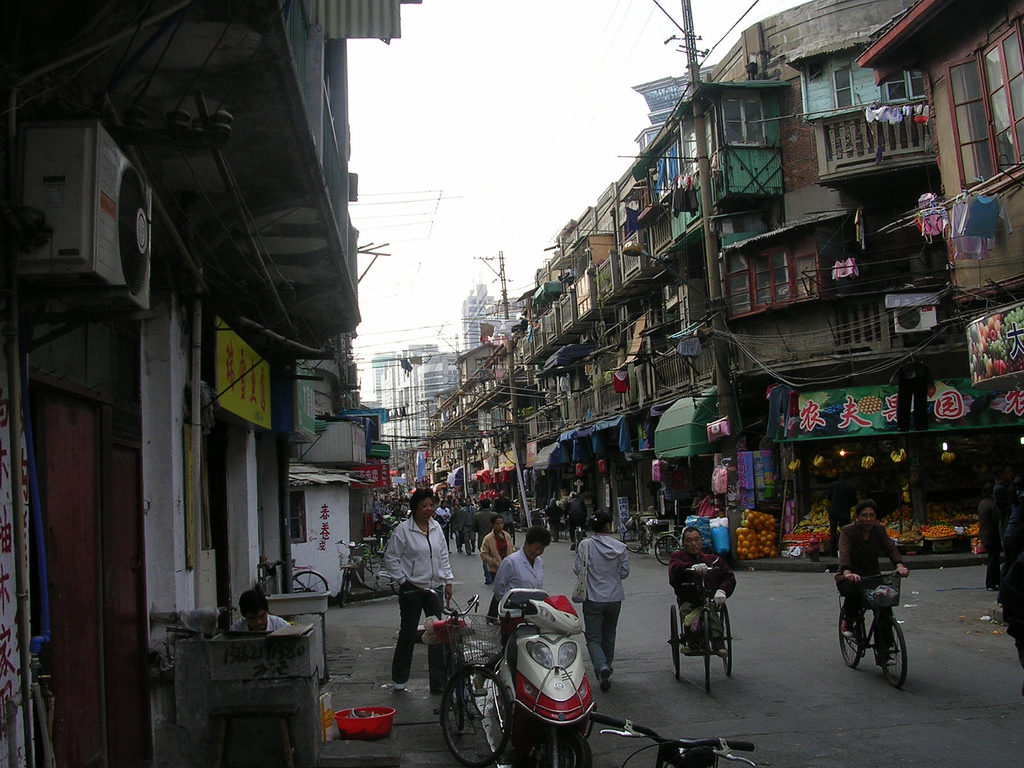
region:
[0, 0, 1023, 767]
An open day in busy street.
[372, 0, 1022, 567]
The street block on the right.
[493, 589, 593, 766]
A red and white colored motor bike.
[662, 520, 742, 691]
The person riding a tricycle.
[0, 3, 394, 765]
The street block on the left.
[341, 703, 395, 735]
A red basin on the street.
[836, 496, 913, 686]
The man cyclist on the right.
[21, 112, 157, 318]
An air conditioning equipment on the wall.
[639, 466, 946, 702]
people are riding bikes in the street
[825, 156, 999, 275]
clothes drying outside of window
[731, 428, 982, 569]
a fruit stand in the background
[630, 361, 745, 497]
a green awning on the building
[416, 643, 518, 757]
the wheel is black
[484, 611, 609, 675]
the headlights are off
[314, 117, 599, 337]
the sky is cloudy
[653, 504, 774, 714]
the bike has three wheels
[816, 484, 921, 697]
A man riding a bicycle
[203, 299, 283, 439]
Red writing on a yellow sign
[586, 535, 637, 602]
the sweater is gray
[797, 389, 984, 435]
the letters are chinese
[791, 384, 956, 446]
Chinese is on the sign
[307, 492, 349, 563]
characters on the building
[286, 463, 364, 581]
the building is shabby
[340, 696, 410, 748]
the container is on sidewalk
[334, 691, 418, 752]
the container is orange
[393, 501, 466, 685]
the person is standing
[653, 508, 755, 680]
man in sweatshirt pedaling cart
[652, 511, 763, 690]
man in sweatshirt pedaling cart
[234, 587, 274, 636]
Head of a man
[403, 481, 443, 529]
Head of a man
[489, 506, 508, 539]
Head of a woman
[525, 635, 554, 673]
Headlight of a motorcycle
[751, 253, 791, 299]
Windows of a building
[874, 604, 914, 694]
Tire of a bike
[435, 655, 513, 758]
Tire of a bike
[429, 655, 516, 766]
Black tire of a bike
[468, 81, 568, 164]
Large body of skies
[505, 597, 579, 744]
a white and red motorcycle